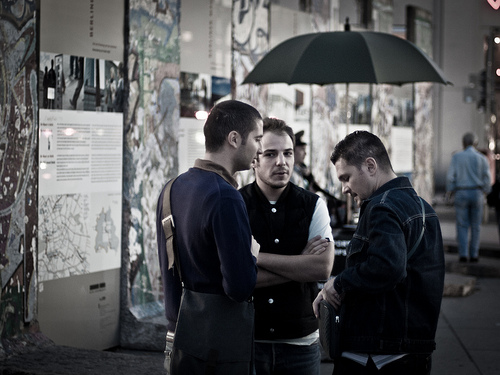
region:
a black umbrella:
[232, 12, 462, 94]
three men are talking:
[134, 82, 461, 362]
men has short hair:
[316, 115, 451, 260]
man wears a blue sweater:
[146, 87, 273, 339]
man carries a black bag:
[144, 93, 273, 365]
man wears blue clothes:
[444, 122, 499, 271]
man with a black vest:
[249, 114, 339, 361]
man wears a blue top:
[307, 125, 450, 372]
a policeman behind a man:
[291, 123, 338, 213]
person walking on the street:
[429, 112, 498, 284]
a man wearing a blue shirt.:
[155, 167, 265, 308]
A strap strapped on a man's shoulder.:
[140, 178, 209, 298]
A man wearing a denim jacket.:
[348, 196, 466, 345]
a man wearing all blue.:
[441, 139, 489, 277]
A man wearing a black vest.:
[248, 181, 332, 352]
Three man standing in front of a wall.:
[126, 77, 467, 367]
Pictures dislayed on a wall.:
[28, 23, 142, 118]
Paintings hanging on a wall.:
[121, 4, 170, 289]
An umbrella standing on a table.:
[275, 38, 442, 123]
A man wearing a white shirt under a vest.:
[310, 205, 341, 266]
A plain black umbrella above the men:
[254, 29, 449, 107]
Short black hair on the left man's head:
[201, 99, 266, 144]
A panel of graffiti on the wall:
[235, 0, 277, 55]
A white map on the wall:
[34, 193, 100, 281]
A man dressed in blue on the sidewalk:
[442, 124, 492, 263]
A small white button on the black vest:
[267, 205, 283, 217]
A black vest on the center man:
[236, 179, 315, 331]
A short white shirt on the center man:
[309, 196, 341, 246]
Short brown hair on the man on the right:
[331, 129, 397, 170]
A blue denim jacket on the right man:
[350, 194, 444, 342]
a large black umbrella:
[238, 15, 461, 96]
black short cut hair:
[326, 131, 396, 176]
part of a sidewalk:
[433, 290, 497, 373]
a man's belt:
[453, 183, 487, 193]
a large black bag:
[166, 285, 257, 373]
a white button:
[271, 205, 277, 213]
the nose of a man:
[275, 148, 287, 167]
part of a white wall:
[444, 3, 481, 71]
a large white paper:
[37, 110, 128, 277]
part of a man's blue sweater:
[157, 165, 258, 327]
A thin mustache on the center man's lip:
[270, 164, 291, 176]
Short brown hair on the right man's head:
[327, 130, 394, 175]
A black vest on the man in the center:
[235, 179, 318, 344]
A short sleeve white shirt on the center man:
[308, 195, 340, 248]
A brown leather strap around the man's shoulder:
[156, 177, 189, 286]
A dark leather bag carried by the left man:
[164, 290, 263, 370]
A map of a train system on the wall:
[36, 189, 125, 280]